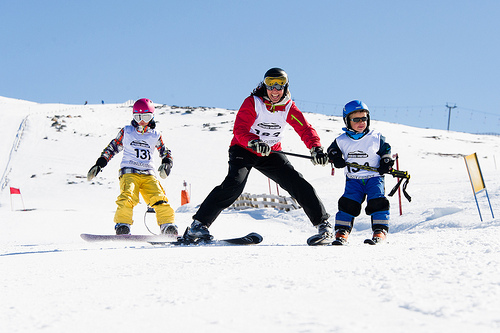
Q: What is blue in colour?
A: The sky.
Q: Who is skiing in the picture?
A: Three people.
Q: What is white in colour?
A: The snow.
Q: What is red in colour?
A: The jacket.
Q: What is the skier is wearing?
A: The black pants.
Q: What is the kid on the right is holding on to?
A: The pole.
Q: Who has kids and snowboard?
A: A person.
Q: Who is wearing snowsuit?
A: Three people.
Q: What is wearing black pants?
A: The person.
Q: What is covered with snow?
A: The mountain.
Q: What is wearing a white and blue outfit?
A: The little boy.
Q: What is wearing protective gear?
A: The child.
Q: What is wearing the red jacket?
A: The woman.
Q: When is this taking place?
A: Daytime.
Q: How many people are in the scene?
A: Three.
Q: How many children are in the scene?
A: Two.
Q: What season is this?
A: Winter.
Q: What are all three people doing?
A: Skiiing.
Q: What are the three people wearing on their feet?
A: Skis.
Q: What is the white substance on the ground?
A: Snow.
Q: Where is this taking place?
A: On the ski slope.